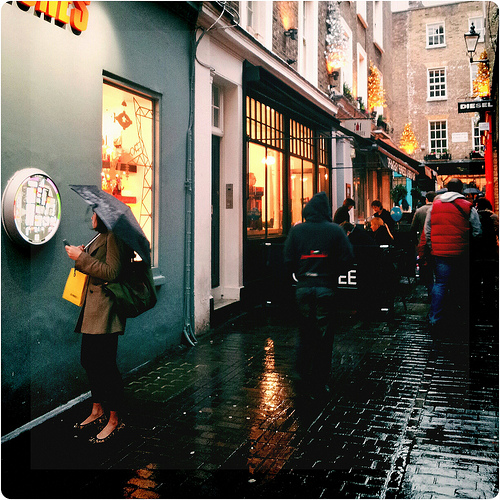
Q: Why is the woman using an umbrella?
A: Its raining.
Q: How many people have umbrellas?
A: 1.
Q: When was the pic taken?
A: During the day.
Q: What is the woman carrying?
A: A bag.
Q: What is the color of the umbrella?
A: Back.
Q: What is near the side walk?
A: A building.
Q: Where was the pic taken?
A: Shopping alleyway.